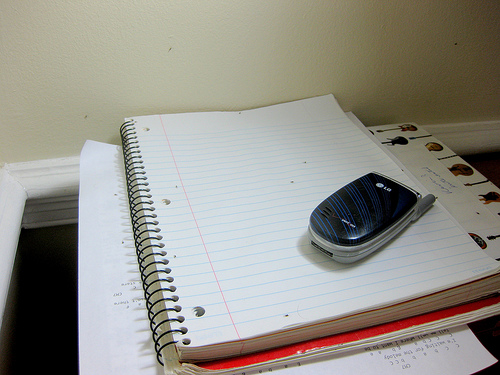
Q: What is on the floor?
A: A notebook.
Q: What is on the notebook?
A: A cellphone.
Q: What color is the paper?
A: White.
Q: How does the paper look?
A: Blank.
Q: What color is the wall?
A: White.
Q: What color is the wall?
A: Tan.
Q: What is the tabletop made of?
A: Glass.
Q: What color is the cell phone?
A: Grey and black.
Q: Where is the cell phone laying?
A: On the notebook.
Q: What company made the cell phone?
A: LG.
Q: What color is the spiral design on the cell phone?
A: Blue.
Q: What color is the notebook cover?
A: Red.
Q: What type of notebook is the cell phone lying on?
A: Spiral.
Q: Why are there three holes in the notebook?
A: For a Three Ring Binder.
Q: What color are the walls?
A: Tan.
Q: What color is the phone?
A: Silver and blue.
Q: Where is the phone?
A: On a notebook.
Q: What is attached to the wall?
A: Molding trim.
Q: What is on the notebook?
A: Cellphone.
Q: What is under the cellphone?
A: Notebook.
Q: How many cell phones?
A: One.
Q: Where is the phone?
A: On the notebook.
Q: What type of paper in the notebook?
A: Lined.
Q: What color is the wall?
A: Tan.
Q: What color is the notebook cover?
A: Red.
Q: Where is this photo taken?
A: At a desk.